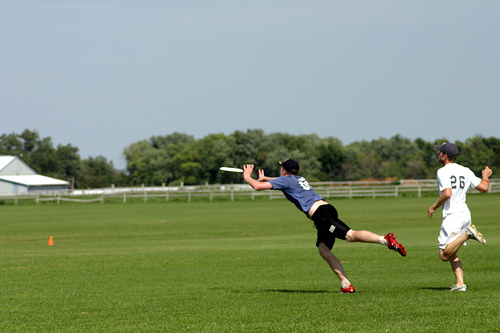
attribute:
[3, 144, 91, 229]
builing — white 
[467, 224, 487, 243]
shoe — red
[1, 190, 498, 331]
grass — green 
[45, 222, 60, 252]
cone — orange 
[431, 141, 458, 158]
hat — gray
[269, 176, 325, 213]
shirt — blue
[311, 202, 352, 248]
shorts — black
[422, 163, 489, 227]
shirt — white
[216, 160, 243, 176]
frisbee — white 